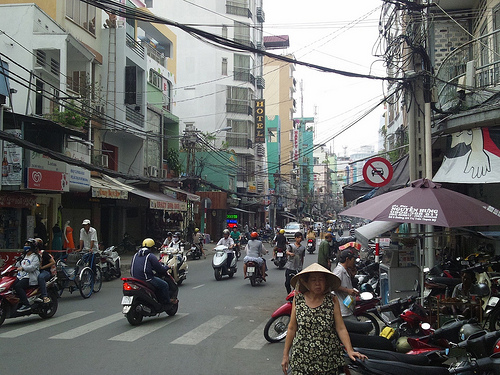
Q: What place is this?
A: It is a city.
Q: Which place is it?
A: It is a city.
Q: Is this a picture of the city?
A: Yes, it is showing the city.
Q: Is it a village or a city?
A: It is a city.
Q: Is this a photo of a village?
A: No, the picture is showing a city.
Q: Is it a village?
A: No, it is a city.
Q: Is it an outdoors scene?
A: Yes, it is outdoors.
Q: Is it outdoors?
A: Yes, it is outdoors.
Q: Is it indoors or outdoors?
A: It is outdoors.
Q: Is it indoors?
A: No, it is outdoors.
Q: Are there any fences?
A: No, there are no fences.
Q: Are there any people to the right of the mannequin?
A: Yes, there is a person to the right of the mannequin.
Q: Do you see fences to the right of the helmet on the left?
A: No, there is a person to the right of the helmet.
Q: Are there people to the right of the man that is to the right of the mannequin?
A: Yes, there is a person to the right of the man.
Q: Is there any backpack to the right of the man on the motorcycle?
A: No, there is a person to the right of the man.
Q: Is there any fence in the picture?
A: No, there are no fences.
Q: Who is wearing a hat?
A: The people are wearing a hat.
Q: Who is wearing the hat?
A: The people are wearing a hat.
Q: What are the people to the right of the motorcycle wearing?
A: The people are wearing a hat.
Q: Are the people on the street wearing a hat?
A: Yes, the people are wearing a hat.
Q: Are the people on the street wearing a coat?
A: No, the people are wearing a hat.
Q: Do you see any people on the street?
A: Yes, there are people on the street.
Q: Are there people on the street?
A: Yes, there are people on the street.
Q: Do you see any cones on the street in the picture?
A: No, there are people on the street.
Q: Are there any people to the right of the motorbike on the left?
A: Yes, there are people to the right of the motorcycle.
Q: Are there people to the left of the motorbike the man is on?
A: No, the people are to the right of the motorcycle.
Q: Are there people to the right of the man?
A: Yes, there are people to the right of the man.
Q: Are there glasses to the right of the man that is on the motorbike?
A: No, there are people to the right of the man.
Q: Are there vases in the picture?
A: No, there are no vases.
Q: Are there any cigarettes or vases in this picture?
A: No, there are no vases or cigarettes.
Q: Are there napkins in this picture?
A: No, there are no napkins.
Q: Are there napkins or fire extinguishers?
A: No, there are no napkins or fire extinguishers.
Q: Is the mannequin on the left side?
A: Yes, the mannequin is on the left of the image.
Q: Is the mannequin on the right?
A: No, the mannequin is on the left of the image.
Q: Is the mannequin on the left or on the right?
A: The mannequin is on the left of the image.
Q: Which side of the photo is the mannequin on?
A: The mannequin is on the left of the image.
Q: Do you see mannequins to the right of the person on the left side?
A: Yes, there is a mannequin to the right of the person.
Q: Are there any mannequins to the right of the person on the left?
A: Yes, there is a mannequin to the right of the person.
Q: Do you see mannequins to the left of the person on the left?
A: No, the mannequin is to the right of the person.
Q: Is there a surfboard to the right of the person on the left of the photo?
A: No, there is a mannequin to the right of the person.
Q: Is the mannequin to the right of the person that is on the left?
A: Yes, the mannequin is to the right of the person.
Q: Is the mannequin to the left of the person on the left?
A: No, the mannequin is to the right of the person.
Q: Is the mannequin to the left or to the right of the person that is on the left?
A: The mannequin is to the right of the person.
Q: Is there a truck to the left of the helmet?
A: No, there is a mannequin to the left of the helmet.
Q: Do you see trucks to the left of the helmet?
A: No, there is a mannequin to the left of the helmet.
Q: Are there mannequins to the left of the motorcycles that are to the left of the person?
A: Yes, there is a mannequin to the left of the motorcycles.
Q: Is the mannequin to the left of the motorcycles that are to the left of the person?
A: Yes, the mannequin is to the left of the motorcycles.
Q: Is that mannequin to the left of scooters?
A: No, the mannequin is to the left of the motorcycles.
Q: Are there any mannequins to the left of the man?
A: Yes, there is a mannequin to the left of the man.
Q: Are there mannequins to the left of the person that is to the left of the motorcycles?
A: Yes, there is a mannequin to the left of the man.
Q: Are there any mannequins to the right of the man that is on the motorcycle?
A: No, the mannequin is to the left of the man.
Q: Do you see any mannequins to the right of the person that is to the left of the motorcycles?
A: No, the mannequin is to the left of the man.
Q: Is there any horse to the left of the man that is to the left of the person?
A: No, there is a mannequin to the left of the man.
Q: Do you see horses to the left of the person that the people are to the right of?
A: No, there is a mannequin to the left of the man.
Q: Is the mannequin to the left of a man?
A: Yes, the mannequin is to the left of a man.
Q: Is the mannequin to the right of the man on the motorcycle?
A: No, the mannequin is to the left of the man.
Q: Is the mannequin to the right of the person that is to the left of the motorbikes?
A: No, the mannequin is to the left of the man.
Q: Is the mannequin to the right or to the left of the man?
A: The mannequin is to the left of the man.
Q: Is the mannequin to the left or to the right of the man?
A: The mannequin is to the left of the man.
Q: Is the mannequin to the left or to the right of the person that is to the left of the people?
A: The mannequin is to the left of the man.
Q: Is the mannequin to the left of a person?
A: Yes, the mannequin is to the left of a person.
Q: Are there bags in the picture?
A: No, there are no bags.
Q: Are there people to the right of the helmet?
A: Yes, there is a person to the right of the helmet.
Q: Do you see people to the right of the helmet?
A: Yes, there is a person to the right of the helmet.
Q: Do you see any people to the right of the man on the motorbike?
A: Yes, there is a person to the right of the man.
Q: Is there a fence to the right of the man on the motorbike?
A: No, there is a person to the right of the man.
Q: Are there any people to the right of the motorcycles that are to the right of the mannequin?
A: Yes, there is a person to the right of the motorbikes.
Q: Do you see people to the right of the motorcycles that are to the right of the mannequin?
A: Yes, there is a person to the right of the motorbikes.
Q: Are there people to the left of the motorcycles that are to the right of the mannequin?
A: No, the person is to the right of the motorbikes.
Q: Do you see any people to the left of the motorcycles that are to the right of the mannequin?
A: No, the person is to the right of the motorbikes.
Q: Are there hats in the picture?
A: Yes, there is a hat.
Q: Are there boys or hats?
A: Yes, there is a hat.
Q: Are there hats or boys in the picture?
A: Yes, there is a hat.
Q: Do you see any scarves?
A: No, there are no scarves.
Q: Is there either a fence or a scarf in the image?
A: No, there are no scarves or fences.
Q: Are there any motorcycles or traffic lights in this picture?
A: Yes, there is a motorcycle.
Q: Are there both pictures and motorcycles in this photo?
A: No, there is a motorcycle but no pictures.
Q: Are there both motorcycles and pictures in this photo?
A: No, there is a motorcycle but no pictures.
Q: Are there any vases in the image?
A: No, there are no vases.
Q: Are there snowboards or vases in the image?
A: No, there are no vases or snowboards.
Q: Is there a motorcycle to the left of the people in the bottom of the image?
A: Yes, there is a motorcycle to the left of the people.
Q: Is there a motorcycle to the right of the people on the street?
A: No, the motorcycle is to the left of the people.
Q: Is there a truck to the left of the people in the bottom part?
A: No, there is a motorcycle to the left of the people.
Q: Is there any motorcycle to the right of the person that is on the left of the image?
A: Yes, there is a motorcycle to the right of the person.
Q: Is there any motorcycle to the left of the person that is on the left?
A: No, the motorcycle is to the right of the person.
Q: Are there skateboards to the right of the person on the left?
A: No, there is a motorcycle to the right of the person.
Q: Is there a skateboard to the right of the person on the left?
A: No, there is a motorcycle to the right of the person.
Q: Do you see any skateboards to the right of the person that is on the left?
A: No, there is a motorcycle to the right of the person.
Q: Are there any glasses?
A: No, there are no glasses.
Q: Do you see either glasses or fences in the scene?
A: No, there are no glasses or fences.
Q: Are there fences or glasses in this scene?
A: No, there are no glasses or fences.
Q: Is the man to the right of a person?
A: No, the man is to the left of a person.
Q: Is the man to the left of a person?
A: Yes, the man is to the left of a person.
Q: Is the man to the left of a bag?
A: No, the man is to the left of a person.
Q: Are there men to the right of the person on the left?
A: Yes, there is a man to the right of the person.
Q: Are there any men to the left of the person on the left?
A: No, the man is to the right of the person.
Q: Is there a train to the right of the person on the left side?
A: No, there is a man to the right of the person.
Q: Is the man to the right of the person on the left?
A: Yes, the man is to the right of the person.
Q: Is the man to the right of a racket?
A: No, the man is to the right of the person.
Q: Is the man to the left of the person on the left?
A: No, the man is to the right of the person.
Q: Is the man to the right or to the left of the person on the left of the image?
A: The man is to the right of the person.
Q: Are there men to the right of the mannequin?
A: Yes, there is a man to the right of the mannequin.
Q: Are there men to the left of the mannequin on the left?
A: No, the man is to the right of the mannequin.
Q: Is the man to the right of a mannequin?
A: Yes, the man is to the right of a mannequin.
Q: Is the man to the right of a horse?
A: No, the man is to the right of a mannequin.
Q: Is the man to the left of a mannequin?
A: No, the man is to the right of a mannequin.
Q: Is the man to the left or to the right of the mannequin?
A: The man is to the right of the mannequin.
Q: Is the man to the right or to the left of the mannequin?
A: The man is to the right of the mannequin.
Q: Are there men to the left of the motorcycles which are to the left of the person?
A: Yes, there is a man to the left of the motorcycles.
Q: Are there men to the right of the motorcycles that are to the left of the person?
A: No, the man is to the left of the motorcycles.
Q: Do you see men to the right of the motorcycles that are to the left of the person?
A: No, the man is to the left of the motorcycles.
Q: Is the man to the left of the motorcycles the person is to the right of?
A: Yes, the man is to the left of the motorbikes.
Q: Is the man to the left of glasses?
A: No, the man is to the left of the motorbikes.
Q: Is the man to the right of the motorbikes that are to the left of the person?
A: No, the man is to the left of the motorbikes.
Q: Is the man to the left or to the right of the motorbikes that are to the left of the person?
A: The man is to the left of the motorcycles.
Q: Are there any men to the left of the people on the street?
A: Yes, there is a man to the left of the people.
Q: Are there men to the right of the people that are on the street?
A: No, the man is to the left of the people.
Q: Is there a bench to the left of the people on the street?
A: No, there is a man to the left of the people.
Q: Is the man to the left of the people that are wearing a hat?
A: Yes, the man is to the left of the people.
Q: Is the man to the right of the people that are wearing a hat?
A: No, the man is to the left of the people.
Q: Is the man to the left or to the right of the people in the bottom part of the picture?
A: The man is to the left of the people.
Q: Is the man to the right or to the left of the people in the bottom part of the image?
A: The man is to the left of the people.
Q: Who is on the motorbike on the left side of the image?
A: The man is on the motorbike.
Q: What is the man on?
A: The man is on the motorbike.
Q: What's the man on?
A: The man is on the motorbike.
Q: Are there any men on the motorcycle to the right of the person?
A: Yes, there is a man on the motorcycle.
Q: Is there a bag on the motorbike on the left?
A: No, there is a man on the motorcycle.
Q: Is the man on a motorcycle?
A: Yes, the man is on a motorcycle.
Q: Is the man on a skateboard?
A: No, the man is on a motorcycle.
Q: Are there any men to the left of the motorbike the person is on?
A: Yes, there is a man to the left of the motorcycle.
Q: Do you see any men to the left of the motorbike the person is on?
A: Yes, there is a man to the left of the motorcycle.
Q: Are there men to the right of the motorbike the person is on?
A: No, the man is to the left of the motorbike.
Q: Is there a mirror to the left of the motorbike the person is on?
A: No, there is a man to the left of the motorbike.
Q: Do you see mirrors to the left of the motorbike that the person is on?
A: No, there is a man to the left of the motorbike.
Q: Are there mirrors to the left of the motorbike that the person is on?
A: No, there is a man to the left of the motorbike.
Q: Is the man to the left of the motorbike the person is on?
A: Yes, the man is to the left of the motorcycle.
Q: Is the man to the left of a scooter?
A: No, the man is to the left of the motorcycle.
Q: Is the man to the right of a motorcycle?
A: No, the man is to the left of a motorcycle.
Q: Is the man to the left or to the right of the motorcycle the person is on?
A: The man is to the left of the motorcycle.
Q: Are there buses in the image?
A: No, there are no buses.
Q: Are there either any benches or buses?
A: No, there are no buses or benches.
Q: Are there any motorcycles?
A: Yes, there are motorcycles.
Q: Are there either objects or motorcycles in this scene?
A: Yes, there are motorcycles.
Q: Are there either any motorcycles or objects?
A: Yes, there are motorcycles.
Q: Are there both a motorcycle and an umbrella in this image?
A: Yes, there are both a motorcycle and an umbrella.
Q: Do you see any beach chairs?
A: No, there are no beach chairs.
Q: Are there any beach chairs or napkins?
A: No, there are no beach chairs or napkins.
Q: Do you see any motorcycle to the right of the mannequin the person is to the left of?
A: Yes, there are motorcycles to the right of the mannequin.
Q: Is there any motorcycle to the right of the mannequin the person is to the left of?
A: Yes, there are motorcycles to the right of the mannequin.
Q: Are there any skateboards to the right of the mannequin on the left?
A: No, there are motorcycles to the right of the mannequin.